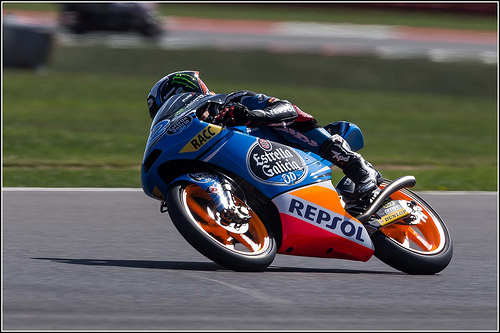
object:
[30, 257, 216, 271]
shadow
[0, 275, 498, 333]
ground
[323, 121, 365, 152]
seat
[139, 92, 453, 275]
motorcycle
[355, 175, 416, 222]
pipe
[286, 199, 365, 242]
ad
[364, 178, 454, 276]
wheel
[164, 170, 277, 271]
wheel